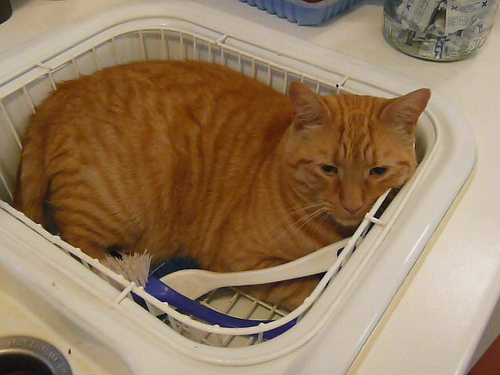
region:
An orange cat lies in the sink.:
[12, 26, 428, 293]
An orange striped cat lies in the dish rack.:
[6, 15, 436, 299]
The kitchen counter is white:
[15, 0, 462, 372]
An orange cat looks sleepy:
[272, 57, 457, 279]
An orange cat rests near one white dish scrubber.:
[18, 55, 452, 325]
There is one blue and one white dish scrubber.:
[82, 227, 367, 349]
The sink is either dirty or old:
[6, 262, 133, 372]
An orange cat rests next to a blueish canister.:
[222, 3, 482, 223]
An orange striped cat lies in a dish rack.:
[15, 35, 431, 336]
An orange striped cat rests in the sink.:
[14, 35, 434, 327]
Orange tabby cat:
[13, 34, 440, 287]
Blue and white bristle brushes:
[85, 243, 380, 343]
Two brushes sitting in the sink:
[87, 230, 380, 326]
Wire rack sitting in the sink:
[2, 25, 428, 352]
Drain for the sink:
[0, 290, 80, 374]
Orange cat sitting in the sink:
[1, 20, 446, 332]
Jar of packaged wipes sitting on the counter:
[372, 1, 499, 65]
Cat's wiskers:
[267, 190, 372, 247]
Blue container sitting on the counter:
[235, 2, 378, 37]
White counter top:
[433, 177, 498, 322]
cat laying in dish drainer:
[44, 66, 435, 301]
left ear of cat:
[383, 87, 426, 129]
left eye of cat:
[370, 160, 390, 177]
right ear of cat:
[285, 80, 333, 123]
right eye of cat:
[315, 160, 336, 173]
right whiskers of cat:
[272, 196, 339, 242]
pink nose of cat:
[340, 196, 363, 216]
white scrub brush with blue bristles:
[142, 235, 352, 310]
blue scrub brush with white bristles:
[90, 252, 303, 334]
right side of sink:
[5, 0, 474, 372]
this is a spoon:
[153, 240, 348, 298]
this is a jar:
[377, 3, 489, 56]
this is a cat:
[26, 67, 386, 239]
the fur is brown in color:
[161, 127, 273, 221]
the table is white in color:
[338, 26, 369, 53]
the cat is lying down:
[40, 99, 377, 295]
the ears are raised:
[287, 84, 429, 131]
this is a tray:
[276, 2, 323, 21]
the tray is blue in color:
[287, 1, 332, 26]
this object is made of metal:
[155, 25, 200, 54]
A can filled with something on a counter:
[386, 2, 499, 62]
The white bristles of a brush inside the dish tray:
[99, 252, 168, 283]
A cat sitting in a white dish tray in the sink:
[18, 52, 440, 309]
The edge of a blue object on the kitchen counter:
[239, 0, 375, 47]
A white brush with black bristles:
[153, 234, 360, 314]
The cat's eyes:
[308, 153, 404, 185]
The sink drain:
[1, 332, 75, 373]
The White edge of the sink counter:
[395, 145, 499, 372]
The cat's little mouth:
[326, 198, 366, 228]